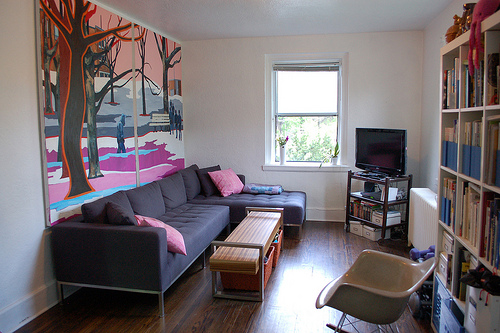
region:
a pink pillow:
[139, 211, 186, 248]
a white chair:
[336, 252, 388, 309]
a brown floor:
[200, 302, 226, 325]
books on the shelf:
[444, 185, 489, 222]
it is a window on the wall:
[272, 70, 328, 145]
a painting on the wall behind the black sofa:
[89, 65, 137, 165]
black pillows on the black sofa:
[101, 196, 136, 222]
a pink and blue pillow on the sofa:
[210, 166, 292, 206]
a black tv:
[348, 128, 413, 167]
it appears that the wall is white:
[375, 40, 412, 86]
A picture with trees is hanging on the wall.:
[26, 6, 201, 219]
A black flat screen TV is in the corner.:
[337, 111, 410, 177]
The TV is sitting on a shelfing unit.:
[336, 160, 422, 242]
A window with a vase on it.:
[237, 35, 357, 175]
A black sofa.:
[65, 155, 307, 316]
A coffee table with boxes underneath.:
[205, 190, 306, 315]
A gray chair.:
[301, 226, 436, 318]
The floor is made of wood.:
[293, 238, 363, 254]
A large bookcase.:
[435, 32, 497, 330]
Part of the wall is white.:
[5, 65, 29, 200]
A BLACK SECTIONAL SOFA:
[46, 158, 310, 319]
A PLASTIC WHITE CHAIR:
[304, 236, 445, 331]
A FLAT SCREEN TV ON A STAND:
[341, 120, 421, 250]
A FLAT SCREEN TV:
[349, 125, 421, 181]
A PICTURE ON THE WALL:
[24, 3, 206, 214]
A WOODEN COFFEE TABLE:
[205, 203, 298, 307]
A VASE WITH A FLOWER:
[266, 126, 299, 175]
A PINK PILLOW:
[129, 210, 193, 260]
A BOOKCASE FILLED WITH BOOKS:
[427, 60, 497, 330]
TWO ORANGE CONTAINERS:
[217, 223, 288, 297]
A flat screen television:
[347, 126, 416, 178]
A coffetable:
[206, 206, 290, 305]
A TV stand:
[340, 167, 411, 242]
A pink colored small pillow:
[207, 170, 247, 197]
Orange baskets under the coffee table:
[226, 213, 293, 293]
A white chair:
[311, 233, 444, 330]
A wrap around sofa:
[47, 160, 313, 310]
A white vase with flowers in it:
[273, 132, 295, 169]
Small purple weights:
[407, 241, 445, 265]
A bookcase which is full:
[427, 14, 499, 331]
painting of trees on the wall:
[26, 5, 204, 202]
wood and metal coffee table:
[210, 204, 292, 316]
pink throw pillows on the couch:
[208, 162, 243, 196]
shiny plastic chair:
[318, 219, 438, 331]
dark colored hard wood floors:
[218, 308, 279, 326]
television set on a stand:
[342, 109, 409, 244]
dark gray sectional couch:
[37, 155, 319, 320]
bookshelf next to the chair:
[432, 5, 498, 325]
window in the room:
[261, 47, 351, 174]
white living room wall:
[192, 62, 249, 154]